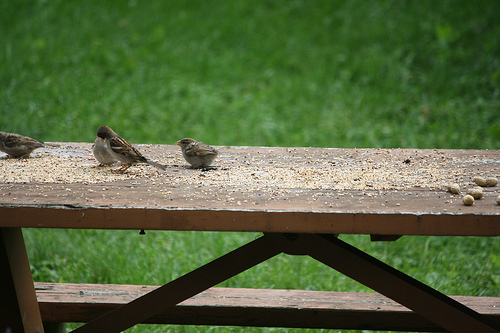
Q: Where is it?
A: This is at the lawn.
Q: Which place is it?
A: It is a lawn.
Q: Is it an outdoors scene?
A: Yes, it is outdoors.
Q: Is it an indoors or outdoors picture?
A: It is outdoors.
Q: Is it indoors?
A: No, it is outdoors.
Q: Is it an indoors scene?
A: No, it is outdoors.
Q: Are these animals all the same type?
A: Yes, all the animals are birds.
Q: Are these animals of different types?
A: No, all the animals are birds.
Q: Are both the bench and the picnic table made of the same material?
A: Yes, both the bench and the picnic table are made of wood.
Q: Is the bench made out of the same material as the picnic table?
A: Yes, both the bench and the picnic table are made of wood.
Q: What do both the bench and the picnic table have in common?
A: The material, both the bench and the picnic table are wooden.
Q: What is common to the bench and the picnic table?
A: The material, both the bench and the picnic table are wooden.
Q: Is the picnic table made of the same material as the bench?
A: Yes, both the picnic table and the bench are made of wood.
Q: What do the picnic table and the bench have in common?
A: The material, both the picnic table and the bench are wooden.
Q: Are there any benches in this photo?
A: Yes, there is a bench.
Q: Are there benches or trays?
A: Yes, there is a bench.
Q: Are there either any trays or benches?
A: Yes, there is a bench.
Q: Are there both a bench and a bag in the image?
A: No, there is a bench but no bags.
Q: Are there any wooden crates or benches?
A: Yes, there is a wood bench.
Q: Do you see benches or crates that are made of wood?
A: Yes, the bench is made of wood.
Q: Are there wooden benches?
A: Yes, there is a wood bench.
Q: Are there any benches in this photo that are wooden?
A: Yes, there is a bench that is wooden.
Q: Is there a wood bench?
A: Yes, there is a bench that is made of wood.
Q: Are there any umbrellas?
A: No, there are no umbrellas.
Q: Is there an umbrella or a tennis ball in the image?
A: No, there are no umbrellas or tennis balls.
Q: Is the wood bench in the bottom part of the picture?
A: Yes, the bench is in the bottom of the image.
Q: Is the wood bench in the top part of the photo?
A: No, the bench is in the bottom of the image.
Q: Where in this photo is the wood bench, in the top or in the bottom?
A: The bench is in the bottom of the image.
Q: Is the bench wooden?
A: Yes, the bench is wooden.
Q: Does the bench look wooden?
A: Yes, the bench is wooden.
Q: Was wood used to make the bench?
A: Yes, the bench is made of wood.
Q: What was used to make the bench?
A: The bench is made of wood.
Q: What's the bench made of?
A: The bench is made of wood.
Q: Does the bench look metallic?
A: No, the bench is wooden.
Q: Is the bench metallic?
A: No, the bench is wooden.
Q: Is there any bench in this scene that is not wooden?
A: No, there is a bench but it is wooden.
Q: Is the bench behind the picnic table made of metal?
A: No, the bench is made of wood.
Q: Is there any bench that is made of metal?
A: No, there is a bench but it is made of wood.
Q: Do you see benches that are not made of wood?
A: No, there is a bench but it is made of wood.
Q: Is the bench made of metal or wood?
A: The bench is made of wood.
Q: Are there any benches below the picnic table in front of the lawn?
A: Yes, there is a bench below the picnic table.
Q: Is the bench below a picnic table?
A: Yes, the bench is below a picnic table.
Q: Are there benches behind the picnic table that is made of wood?
A: Yes, there is a bench behind the picnic table.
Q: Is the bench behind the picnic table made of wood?
A: Yes, the bench is behind the picnic table.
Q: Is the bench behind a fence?
A: No, the bench is behind the picnic table.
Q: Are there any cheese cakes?
A: No, there are no cheese cakes.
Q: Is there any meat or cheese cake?
A: No, there are no cheesecakes or meat.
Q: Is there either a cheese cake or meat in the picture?
A: No, there are no cheesecakes or meat.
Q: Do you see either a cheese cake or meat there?
A: No, there are no cheesecakes or meat.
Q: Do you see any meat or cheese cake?
A: No, there are no cheesecakes or meat.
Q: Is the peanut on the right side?
A: Yes, the peanut is on the right of the image.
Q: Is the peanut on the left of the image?
A: No, the peanut is on the right of the image.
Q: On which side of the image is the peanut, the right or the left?
A: The peanut is on the right of the image.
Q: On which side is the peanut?
A: The peanut is on the right of the image.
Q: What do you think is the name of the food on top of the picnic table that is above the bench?
A: The food is a peanut.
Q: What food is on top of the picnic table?
A: The food is a peanut.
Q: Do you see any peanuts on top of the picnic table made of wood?
A: Yes, there is a peanut on top of the picnic table.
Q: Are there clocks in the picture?
A: No, there are no clocks.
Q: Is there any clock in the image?
A: No, there are no clocks.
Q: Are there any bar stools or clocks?
A: No, there are no clocks or bar stools.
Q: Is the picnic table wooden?
A: Yes, the picnic table is wooden.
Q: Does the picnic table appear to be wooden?
A: Yes, the picnic table is wooden.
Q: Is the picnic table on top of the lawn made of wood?
A: Yes, the picnic table is made of wood.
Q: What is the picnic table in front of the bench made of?
A: The picnic table is made of wood.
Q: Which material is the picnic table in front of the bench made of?
A: The picnic table is made of wood.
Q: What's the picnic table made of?
A: The picnic table is made of wood.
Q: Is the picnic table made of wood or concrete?
A: The picnic table is made of wood.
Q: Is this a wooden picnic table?
A: Yes, this is a wooden picnic table.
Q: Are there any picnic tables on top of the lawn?
A: Yes, there is a picnic table on top of the lawn.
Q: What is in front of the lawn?
A: The picnic table is in front of the lawn.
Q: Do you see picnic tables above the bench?
A: Yes, there is a picnic table above the bench.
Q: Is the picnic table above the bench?
A: Yes, the picnic table is above the bench.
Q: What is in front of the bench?
A: The picnic table is in front of the bench.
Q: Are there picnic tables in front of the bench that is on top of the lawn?
A: Yes, there is a picnic table in front of the bench.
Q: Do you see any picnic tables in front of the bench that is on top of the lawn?
A: Yes, there is a picnic table in front of the bench.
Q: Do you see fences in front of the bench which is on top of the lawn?
A: No, there is a picnic table in front of the bench.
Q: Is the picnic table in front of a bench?
A: Yes, the picnic table is in front of a bench.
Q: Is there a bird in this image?
A: Yes, there is a bird.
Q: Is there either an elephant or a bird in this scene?
A: Yes, there is a bird.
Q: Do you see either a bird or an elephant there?
A: Yes, there is a bird.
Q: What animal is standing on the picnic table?
A: The bird is standing on the picnic table.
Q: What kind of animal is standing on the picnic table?
A: The animal is a bird.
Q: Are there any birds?
A: Yes, there is a bird.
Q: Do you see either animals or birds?
A: Yes, there is a bird.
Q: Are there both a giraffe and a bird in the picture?
A: No, there is a bird but no giraffes.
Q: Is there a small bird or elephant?
A: Yes, there is a small bird.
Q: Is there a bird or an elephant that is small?
A: Yes, the bird is small.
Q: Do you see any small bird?
A: Yes, there is a small bird.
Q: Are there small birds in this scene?
A: Yes, there is a small bird.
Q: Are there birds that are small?
A: Yes, there is a bird that is small.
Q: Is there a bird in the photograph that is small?
A: Yes, there is a bird that is small.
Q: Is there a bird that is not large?
A: Yes, there is a small bird.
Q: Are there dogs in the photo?
A: No, there are no dogs.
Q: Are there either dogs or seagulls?
A: No, there are no dogs or seagulls.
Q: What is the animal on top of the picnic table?
A: The animal is a bird.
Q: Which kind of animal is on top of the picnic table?
A: The animal is a bird.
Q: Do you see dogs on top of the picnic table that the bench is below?
A: No, there is a bird on top of the picnic table.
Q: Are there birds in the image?
A: Yes, there is a bird.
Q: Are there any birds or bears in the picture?
A: Yes, there is a bird.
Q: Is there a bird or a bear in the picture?
A: Yes, there is a bird.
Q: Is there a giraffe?
A: No, there are no giraffes.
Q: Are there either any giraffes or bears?
A: No, there are no giraffes or bears.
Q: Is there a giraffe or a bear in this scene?
A: No, there are no giraffes or bears.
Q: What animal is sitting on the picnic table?
A: The bird is sitting on the picnic table.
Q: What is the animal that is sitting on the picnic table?
A: The animal is a bird.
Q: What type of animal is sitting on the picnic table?
A: The animal is a bird.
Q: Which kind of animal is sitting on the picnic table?
A: The animal is a bird.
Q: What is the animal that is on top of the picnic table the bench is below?
A: The animal is a bird.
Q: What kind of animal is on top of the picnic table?
A: The animal is a bird.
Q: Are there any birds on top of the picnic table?
A: Yes, there is a bird on top of the picnic table.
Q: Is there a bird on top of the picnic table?
A: Yes, there is a bird on top of the picnic table.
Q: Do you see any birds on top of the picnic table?
A: Yes, there is a bird on top of the picnic table.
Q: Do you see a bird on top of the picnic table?
A: Yes, there is a bird on top of the picnic table.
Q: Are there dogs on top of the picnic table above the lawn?
A: No, there is a bird on top of the picnic table.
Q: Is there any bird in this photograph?
A: Yes, there is a bird.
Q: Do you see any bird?
A: Yes, there is a bird.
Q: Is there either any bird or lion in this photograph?
A: Yes, there is a bird.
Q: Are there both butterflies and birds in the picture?
A: No, there is a bird but no butterflies.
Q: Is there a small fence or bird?
A: Yes, there is a small bird.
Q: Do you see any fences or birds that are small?
A: Yes, the bird is small.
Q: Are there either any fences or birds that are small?
A: Yes, the bird is small.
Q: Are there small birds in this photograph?
A: Yes, there is a small bird.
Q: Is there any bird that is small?
A: Yes, there is a bird that is small.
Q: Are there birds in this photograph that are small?
A: Yes, there is a bird that is small.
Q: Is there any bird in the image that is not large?
A: Yes, there is a small bird.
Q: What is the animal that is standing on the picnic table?
A: The animal is a bird.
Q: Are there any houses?
A: No, there are no houses.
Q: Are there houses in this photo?
A: No, there are no houses.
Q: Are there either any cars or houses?
A: No, there are no houses or cars.